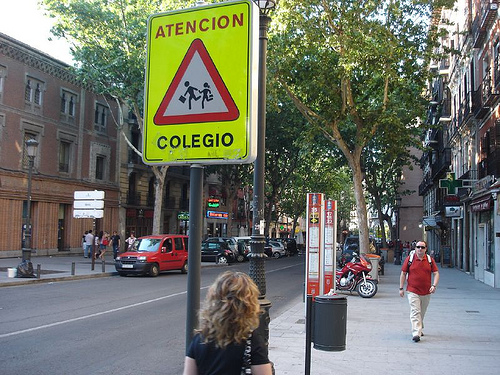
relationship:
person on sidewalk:
[397, 236, 440, 344] [267, 257, 485, 373]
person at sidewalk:
[397, 236, 440, 344] [267, 257, 485, 373]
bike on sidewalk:
[334, 250, 378, 300] [267, 257, 485, 373]